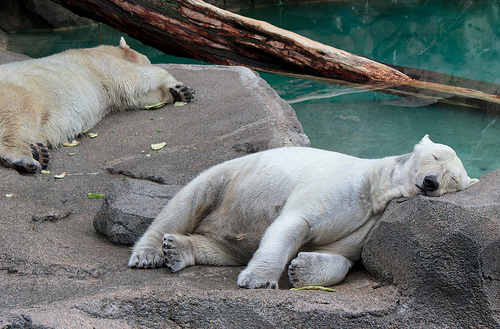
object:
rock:
[91, 175, 187, 245]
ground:
[0, 34, 499, 328]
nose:
[421, 174, 440, 192]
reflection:
[289, 0, 500, 86]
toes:
[126, 252, 139, 269]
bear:
[127, 130, 479, 295]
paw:
[282, 249, 330, 288]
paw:
[159, 232, 199, 274]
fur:
[237, 167, 287, 204]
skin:
[319, 163, 361, 212]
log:
[55, 0, 499, 113]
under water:
[0, 0, 499, 182]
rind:
[145, 140, 169, 151]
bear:
[1, 35, 199, 175]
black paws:
[167, 81, 198, 104]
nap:
[126, 130, 482, 290]